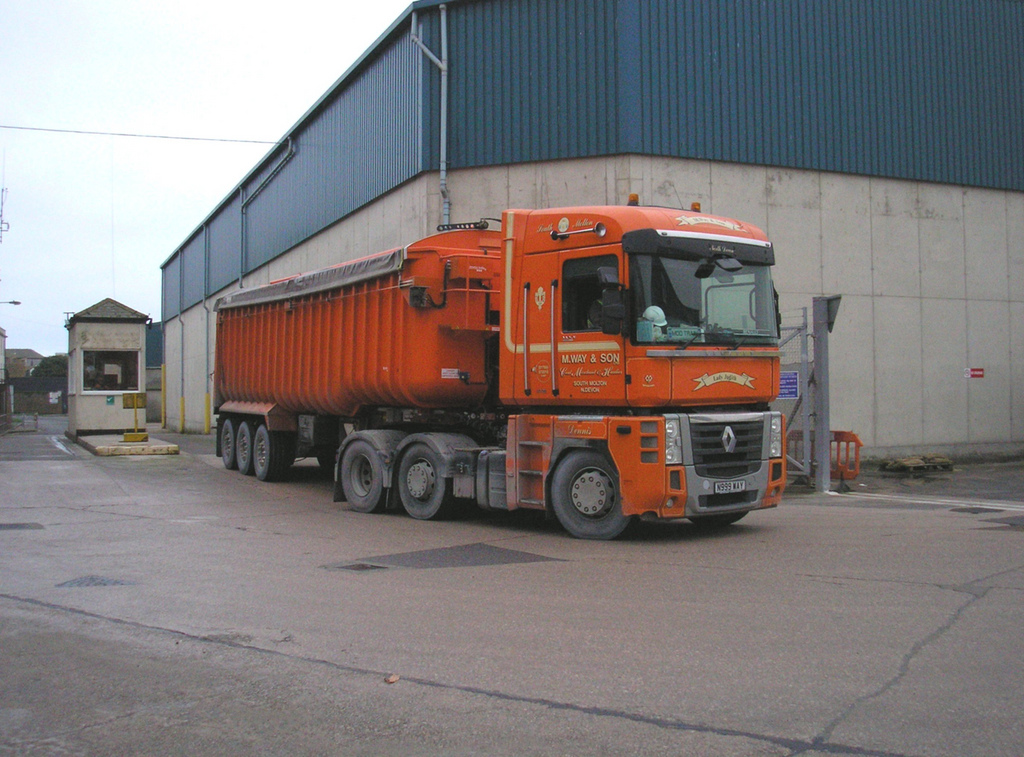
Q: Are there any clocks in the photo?
A: No, there are no clocks.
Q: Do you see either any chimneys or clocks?
A: No, there are no clocks or chimneys.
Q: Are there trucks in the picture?
A: Yes, there is a truck.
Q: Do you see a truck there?
A: Yes, there is a truck.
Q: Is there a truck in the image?
A: Yes, there is a truck.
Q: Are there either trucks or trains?
A: Yes, there is a truck.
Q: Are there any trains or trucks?
A: Yes, there is a truck.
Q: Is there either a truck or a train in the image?
A: Yes, there is a truck.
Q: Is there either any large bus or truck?
A: Yes, there is a large truck.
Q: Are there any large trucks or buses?
A: Yes, there is a large truck.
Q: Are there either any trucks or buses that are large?
A: Yes, the truck is large.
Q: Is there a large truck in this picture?
A: Yes, there is a large truck.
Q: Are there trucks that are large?
A: Yes, there is a truck that is large.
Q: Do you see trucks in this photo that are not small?
A: Yes, there is a large truck.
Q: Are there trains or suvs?
A: No, there are no trains or suvs.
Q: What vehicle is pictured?
A: The vehicle is a truck.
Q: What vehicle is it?
A: The vehicle is a truck.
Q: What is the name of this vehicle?
A: This is a truck.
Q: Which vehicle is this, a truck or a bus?
A: This is a truck.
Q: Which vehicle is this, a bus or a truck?
A: This is a truck.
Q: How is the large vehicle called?
A: The vehicle is a truck.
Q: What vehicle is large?
A: The vehicle is a truck.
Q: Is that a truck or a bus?
A: That is a truck.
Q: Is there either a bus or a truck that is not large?
A: No, there is a truck but it is large.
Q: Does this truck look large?
A: Yes, the truck is large.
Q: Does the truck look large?
A: Yes, the truck is large.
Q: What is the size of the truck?
A: The truck is large.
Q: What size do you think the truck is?
A: The truck is large.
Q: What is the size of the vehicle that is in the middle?
A: The truck is large.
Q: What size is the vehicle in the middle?
A: The truck is large.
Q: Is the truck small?
A: No, the truck is large.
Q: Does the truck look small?
A: No, the truck is large.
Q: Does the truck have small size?
A: No, the truck is large.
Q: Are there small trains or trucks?
A: No, there is a truck but it is large.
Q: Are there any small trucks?
A: No, there is a truck but it is large.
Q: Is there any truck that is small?
A: No, there is a truck but it is large.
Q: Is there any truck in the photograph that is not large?
A: No, there is a truck but it is large.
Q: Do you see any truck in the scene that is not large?
A: No, there is a truck but it is large.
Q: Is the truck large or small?
A: The truck is large.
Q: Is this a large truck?
A: Yes, this is a large truck.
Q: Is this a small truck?
A: No, this is a large truck.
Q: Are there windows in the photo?
A: Yes, there is a window.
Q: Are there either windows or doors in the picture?
A: Yes, there is a window.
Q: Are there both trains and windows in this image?
A: No, there is a window but no trains.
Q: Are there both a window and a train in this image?
A: No, there is a window but no trains.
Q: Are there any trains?
A: No, there are no trains.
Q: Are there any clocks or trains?
A: No, there are no trains or clocks.